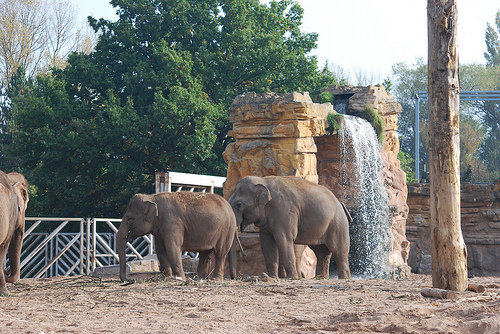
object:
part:
[200, 33, 252, 63]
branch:
[240, 54, 315, 92]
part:
[37, 218, 83, 257]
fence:
[0, 162, 234, 283]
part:
[430, 0, 470, 291]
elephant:
[117, 193, 240, 279]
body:
[154, 198, 236, 249]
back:
[157, 193, 224, 203]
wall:
[381, 185, 499, 268]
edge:
[20, 216, 91, 289]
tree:
[4, 2, 312, 284]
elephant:
[230, 177, 354, 280]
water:
[336, 113, 399, 275]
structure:
[203, 84, 414, 278]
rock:
[227, 120, 299, 137]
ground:
[4, 251, 499, 331]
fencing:
[24, 217, 144, 276]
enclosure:
[2, 2, 495, 331]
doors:
[14, 176, 164, 279]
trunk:
[117, 222, 133, 282]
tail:
[234, 212, 249, 257]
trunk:
[230, 207, 238, 281]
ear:
[138, 199, 161, 218]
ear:
[249, 182, 274, 203]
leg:
[164, 227, 189, 280]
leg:
[270, 216, 300, 279]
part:
[415, 82, 421, 183]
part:
[127, 191, 165, 234]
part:
[227, 88, 396, 171]